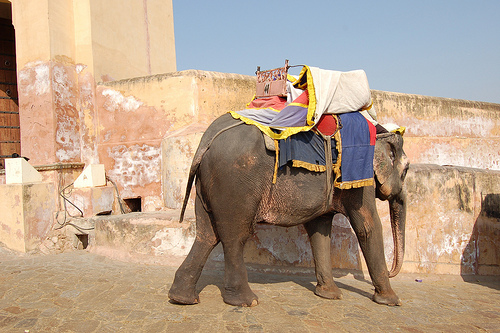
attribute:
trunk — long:
[381, 191, 411, 279]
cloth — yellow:
[304, 65, 372, 122]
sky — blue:
[172, 3, 499, 105]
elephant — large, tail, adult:
[163, 104, 414, 306]